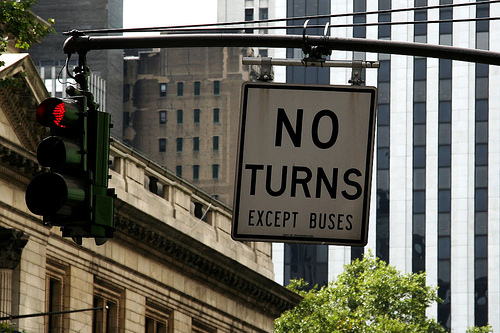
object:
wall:
[0, 244, 263, 332]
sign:
[228, 77, 380, 247]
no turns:
[245, 105, 364, 203]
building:
[0, 0, 125, 145]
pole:
[58, 29, 500, 65]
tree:
[0, 0, 53, 49]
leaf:
[396, 280, 408, 294]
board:
[230, 79, 380, 247]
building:
[122, 19, 269, 215]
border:
[231, 80, 380, 247]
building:
[0, 46, 310, 333]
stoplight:
[22, 84, 118, 249]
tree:
[269, 253, 453, 333]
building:
[218, 0, 498, 333]